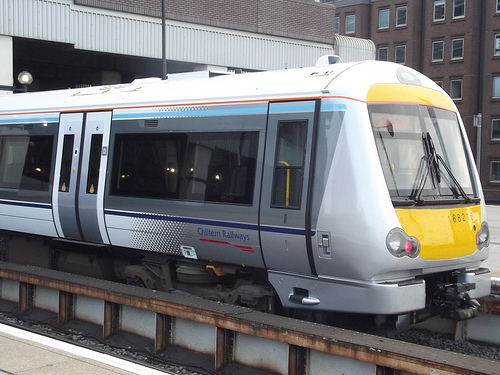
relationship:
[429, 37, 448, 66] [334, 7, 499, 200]
window on building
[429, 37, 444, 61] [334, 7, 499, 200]
window on building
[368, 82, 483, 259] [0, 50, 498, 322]
yellow paint on train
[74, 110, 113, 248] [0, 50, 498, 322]
door on side of train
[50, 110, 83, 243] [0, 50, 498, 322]
door on side of train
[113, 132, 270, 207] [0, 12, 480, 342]
window on train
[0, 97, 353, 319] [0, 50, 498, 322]
side of train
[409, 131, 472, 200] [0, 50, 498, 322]
wipers on train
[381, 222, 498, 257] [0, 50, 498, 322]
light on train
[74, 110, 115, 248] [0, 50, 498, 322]
door on train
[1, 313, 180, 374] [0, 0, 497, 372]
platform of station